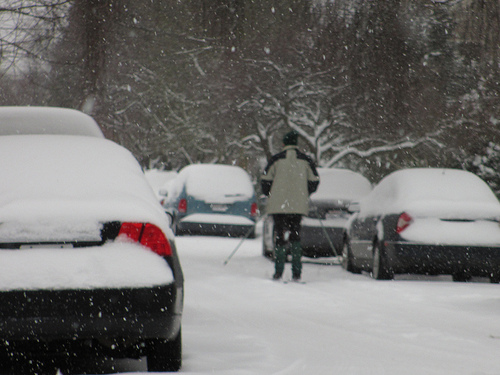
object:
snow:
[92, 234, 500, 373]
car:
[0, 105, 187, 373]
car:
[341, 166, 499, 283]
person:
[259, 131, 320, 282]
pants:
[271, 214, 302, 279]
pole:
[310, 200, 345, 267]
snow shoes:
[283, 273, 303, 284]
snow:
[2, 106, 175, 289]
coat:
[257, 146, 319, 218]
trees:
[0, 1, 500, 209]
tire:
[342, 242, 360, 271]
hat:
[283, 131, 303, 145]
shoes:
[269, 270, 285, 279]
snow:
[344, 167, 498, 243]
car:
[263, 166, 372, 260]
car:
[160, 162, 260, 239]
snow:
[165, 162, 253, 202]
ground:
[115, 233, 499, 374]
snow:
[297, 167, 372, 227]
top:
[259, 146, 320, 212]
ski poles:
[220, 217, 260, 268]